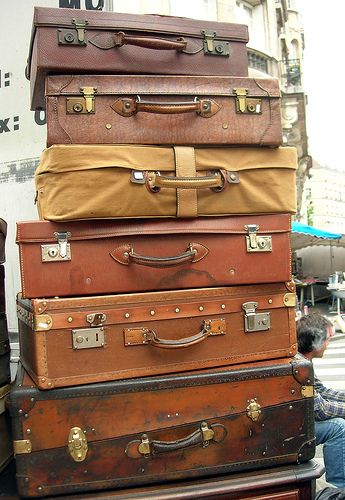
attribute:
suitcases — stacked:
[5, 3, 329, 498]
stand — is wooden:
[48, 456, 324, 498]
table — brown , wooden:
[0, 227, 16, 360]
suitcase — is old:
[18, 217, 299, 285]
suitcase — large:
[12, 372, 318, 479]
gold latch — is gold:
[67, 423, 89, 459]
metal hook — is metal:
[67, 327, 108, 353]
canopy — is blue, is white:
[287, 209, 340, 253]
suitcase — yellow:
[51, 145, 295, 212]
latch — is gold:
[63, 424, 88, 462]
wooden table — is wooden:
[88, 455, 328, 498]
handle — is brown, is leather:
[110, 34, 198, 56]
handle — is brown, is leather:
[112, 99, 218, 121]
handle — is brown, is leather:
[134, 170, 234, 190]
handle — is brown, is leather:
[135, 324, 233, 350]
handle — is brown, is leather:
[130, 427, 210, 456]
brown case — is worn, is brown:
[5, 378, 315, 496]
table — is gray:
[293, 276, 319, 307]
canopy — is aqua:
[289, 220, 339, 246]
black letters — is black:
[60, 0, 110, 13]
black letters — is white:
[2, 106, 48, 133]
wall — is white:
[0, 0, 113, 303]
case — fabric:
[34, 142, 281, 221]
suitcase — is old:
[17, 290, 296, 388]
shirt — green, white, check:
[314, 374, 344, 420]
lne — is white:
[306, 353, 344, 371]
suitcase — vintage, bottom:
[26, 3, 252, 84]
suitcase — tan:
[34, 142, 299, 214]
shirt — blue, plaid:
[295, 349, 344, 419]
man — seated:
[297, 309, 340, 490]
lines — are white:
[309, 316, 343, 390]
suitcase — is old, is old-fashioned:
[43, 74, 282, 144]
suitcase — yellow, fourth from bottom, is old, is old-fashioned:
[39, 145, 298, 218]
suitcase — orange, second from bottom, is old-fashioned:
[32, 282, 297, 389]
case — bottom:
[9, 356, 306, 474]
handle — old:
[135, 429, 220, 461]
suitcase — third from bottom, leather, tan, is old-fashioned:
[14, 213, 295, 297]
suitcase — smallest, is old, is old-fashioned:
[23, 11, 251, 112]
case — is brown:
[16, 278, 295, 386]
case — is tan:
[13, 210, 294, 297]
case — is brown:
[34, 144, 298, 219]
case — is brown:
[14, 4, 248, 75]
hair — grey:
[295, 313, 324, 353]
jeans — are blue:
[307, 415, 343, 489]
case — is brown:
[13, 351, 314, 495]